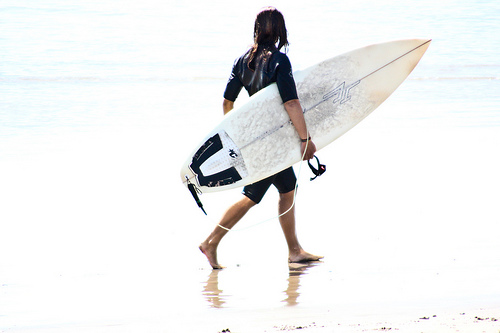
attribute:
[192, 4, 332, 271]
man — light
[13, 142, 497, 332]
beach — shore, wet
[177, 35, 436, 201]
surfboard — big, white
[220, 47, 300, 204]
wetsuit — black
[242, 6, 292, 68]
hair — long, wet, black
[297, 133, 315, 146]
wristband — black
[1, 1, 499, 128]
water — blue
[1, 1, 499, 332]
photo — bright